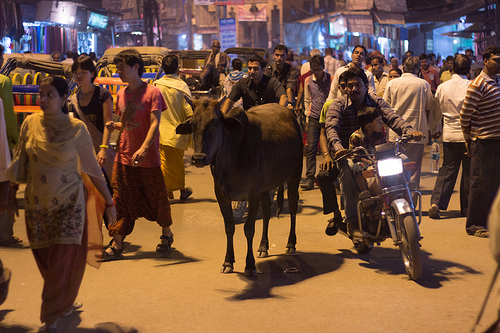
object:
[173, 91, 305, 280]
cow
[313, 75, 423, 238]
men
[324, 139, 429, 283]
motorcycle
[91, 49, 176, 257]
man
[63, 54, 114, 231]
woman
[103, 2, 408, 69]
buildings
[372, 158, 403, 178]
headlight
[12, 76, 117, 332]
girl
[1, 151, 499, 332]
street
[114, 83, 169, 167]
shirt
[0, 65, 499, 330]
square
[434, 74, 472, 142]
shirt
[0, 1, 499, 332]
market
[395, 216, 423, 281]
wheel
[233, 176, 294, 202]
stomach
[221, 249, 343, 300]
shade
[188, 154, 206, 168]
mouth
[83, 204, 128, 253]
cloth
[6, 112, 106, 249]
skirt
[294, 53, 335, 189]
crowd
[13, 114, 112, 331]
outfit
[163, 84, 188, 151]
yellow